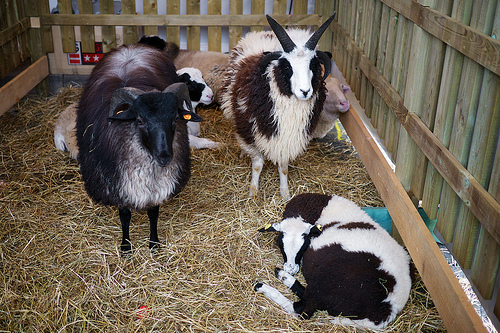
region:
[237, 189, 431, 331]
Sheep laying down in the hay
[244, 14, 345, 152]
Sheep with tall straight horns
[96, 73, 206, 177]
Sheep with black curved horns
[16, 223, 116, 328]
Fresh hay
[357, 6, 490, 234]
Wooden slatted walls of a pen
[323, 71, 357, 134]
Beige sheep laying down in the back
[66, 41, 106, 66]
A red, white and blue sign with stars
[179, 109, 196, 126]
Yellow tag in the sheep's ear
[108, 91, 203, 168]
Sheep with a black face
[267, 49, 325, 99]
Sheep with black and white face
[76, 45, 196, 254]
goat with curved horns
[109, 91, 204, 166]
goat has a black face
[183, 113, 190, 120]
orange tag on goat ear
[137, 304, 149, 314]
red object in straw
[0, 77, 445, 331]
straw is tan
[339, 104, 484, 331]
wood rail surrounding pen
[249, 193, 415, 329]
calf is sleeping on straw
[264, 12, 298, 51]
black pointy horns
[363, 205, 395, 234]
blue fabric under calf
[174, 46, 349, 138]
sheep behind goat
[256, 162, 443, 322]
the goat is sleeping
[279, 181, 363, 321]
the goat is sleeping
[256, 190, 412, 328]
A brown and white goat lying on the ground.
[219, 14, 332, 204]
A brown black and white goat with large black horns.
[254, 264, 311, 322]
Two back legs of a goat lying on the ground.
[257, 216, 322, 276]
Head of a brown and white goat lying on the ground.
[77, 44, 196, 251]
A shaggy black, brown and white goat standing to the left of a goat lying on the ground.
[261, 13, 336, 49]
Two large black horns on a goats head.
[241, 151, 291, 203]
Two thin white legs on a goat with large horns that point up.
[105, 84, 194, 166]
The black head of a ram.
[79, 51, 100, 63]
Two stars behind a ram.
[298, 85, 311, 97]
Tiny black nose on a goat with large black horns.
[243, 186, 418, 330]
sheep lying in the hay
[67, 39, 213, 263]
brown ram standing on hay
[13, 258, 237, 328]
hay in the stall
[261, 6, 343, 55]
horns of a ram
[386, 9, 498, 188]
wooden wall of a stall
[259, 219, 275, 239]
yellow tag on sheep's ear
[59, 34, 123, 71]
sticker on back wall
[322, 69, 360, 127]
sheeps head in the background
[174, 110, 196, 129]
orange tag on ram's ear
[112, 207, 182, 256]
front legs of a ram